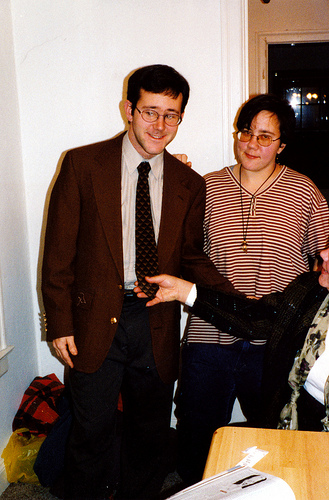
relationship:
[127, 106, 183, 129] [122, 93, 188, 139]
pair of glasses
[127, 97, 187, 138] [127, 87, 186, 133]
pair of glasses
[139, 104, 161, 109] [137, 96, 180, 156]
eyebrow on face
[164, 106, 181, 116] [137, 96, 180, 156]
eyebrow on face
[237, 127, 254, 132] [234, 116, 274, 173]
eyebrow on face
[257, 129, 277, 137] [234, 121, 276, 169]
eyebrow on face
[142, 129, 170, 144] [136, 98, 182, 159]
mouth on face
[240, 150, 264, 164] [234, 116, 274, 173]
mouth on face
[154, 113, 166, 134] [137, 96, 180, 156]
nose on face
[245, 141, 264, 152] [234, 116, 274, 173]
nose on face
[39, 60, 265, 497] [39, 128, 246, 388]
man in jacket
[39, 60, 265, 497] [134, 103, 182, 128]
man wearing glasses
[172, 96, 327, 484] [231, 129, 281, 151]
person wearing glasses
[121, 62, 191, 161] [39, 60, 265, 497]
head of man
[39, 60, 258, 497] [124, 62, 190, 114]
man has hair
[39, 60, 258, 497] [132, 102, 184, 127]
man wearing glasses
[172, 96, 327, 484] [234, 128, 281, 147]
person wearing glasses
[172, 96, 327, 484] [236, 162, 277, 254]
person wearing chain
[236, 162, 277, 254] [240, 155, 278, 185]
chain around neck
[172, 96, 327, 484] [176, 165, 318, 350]
person wearing shirt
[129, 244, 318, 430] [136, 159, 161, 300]
person holding tie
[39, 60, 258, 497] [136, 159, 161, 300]
man has tie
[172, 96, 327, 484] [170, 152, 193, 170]
person has hand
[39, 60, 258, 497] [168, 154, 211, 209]
man has shoulder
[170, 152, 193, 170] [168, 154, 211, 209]
hand on shoulder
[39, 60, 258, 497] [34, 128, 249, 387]
man wearing jacket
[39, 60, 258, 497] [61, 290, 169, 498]
man wearing pants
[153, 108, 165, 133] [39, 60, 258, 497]
nose on man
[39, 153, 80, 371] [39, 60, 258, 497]
arm on man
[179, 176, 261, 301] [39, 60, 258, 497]
arm on man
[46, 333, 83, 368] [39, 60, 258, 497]
hand on man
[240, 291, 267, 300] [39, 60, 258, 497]
hand on man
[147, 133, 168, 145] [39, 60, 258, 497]
mouth on man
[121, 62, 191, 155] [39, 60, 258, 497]
head on man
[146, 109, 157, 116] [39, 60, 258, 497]
eye on man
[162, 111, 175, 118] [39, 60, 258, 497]
eye on man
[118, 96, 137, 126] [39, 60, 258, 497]
ear on man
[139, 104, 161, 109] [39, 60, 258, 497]
eyebrow on man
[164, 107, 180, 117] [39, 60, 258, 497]
eyebrow on man